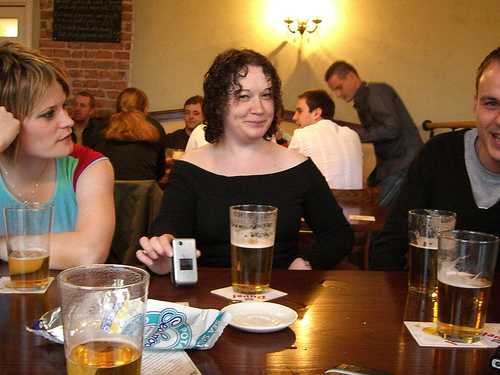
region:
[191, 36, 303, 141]
face of the girl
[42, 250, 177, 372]
a glass of wine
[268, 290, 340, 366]
light on the table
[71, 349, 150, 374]
half glass of wine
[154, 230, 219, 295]
a small mobile phone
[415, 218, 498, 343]
a series of glasses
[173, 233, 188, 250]
camera of the mobile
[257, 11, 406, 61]
light connected to wall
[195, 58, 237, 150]
hairs of the girls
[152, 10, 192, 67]
this is the wall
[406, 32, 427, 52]
the wall is white in color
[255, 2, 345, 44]
these are some bulbs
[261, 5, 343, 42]
the lights are bright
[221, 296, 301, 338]
this is a saucer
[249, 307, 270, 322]
the saucer is white in color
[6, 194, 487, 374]
these are some cups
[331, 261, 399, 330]
this is a table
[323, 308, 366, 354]
the table is wooden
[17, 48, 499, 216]
these are several people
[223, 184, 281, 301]
Clear cup sitting on a table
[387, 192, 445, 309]
Clear cup sitting on a table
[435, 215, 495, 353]
Clear cup sitting on a table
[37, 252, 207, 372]
Clear cup sitting on a table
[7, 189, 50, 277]
Clear cup sitting on a table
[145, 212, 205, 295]
White cell ohone in womans hands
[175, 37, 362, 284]
Woman sitting at a table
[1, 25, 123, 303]
Woman sitting at a table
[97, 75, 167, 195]
Woman sitting at a table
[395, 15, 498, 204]
Man sitting at a table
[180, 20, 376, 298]
Person sitting at a table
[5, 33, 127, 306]
Part of a green hedge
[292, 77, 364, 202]
Part of a green hedge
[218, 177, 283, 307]
Brown liquid in clear glass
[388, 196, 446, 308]
Brown liquid in clear glass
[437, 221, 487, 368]
Brown liquid in clear glass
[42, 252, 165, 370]
Brown liquid in clear glass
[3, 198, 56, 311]
Brown liquid in clear glass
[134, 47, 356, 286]
Woman holding up cell phone on table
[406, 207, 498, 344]
Glasses of beet on table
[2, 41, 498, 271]
Man and two women sitting at table in restaurant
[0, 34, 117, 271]
Blonde-haired woman looking to her left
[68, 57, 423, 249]
People gathered around table by the wall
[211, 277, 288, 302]
Napkin under beer glass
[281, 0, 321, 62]
Lamp on the wall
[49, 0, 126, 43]
Menu items written on blackboard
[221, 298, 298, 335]
White saucer on the table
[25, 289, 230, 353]
Potato chip bag on the table